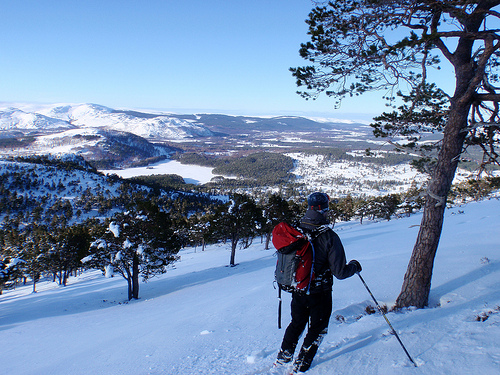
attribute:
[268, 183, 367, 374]
man — skiing, shadowing, here, standing, shadowy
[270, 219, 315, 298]
backpack — red, here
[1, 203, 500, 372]
slope — snowy, here, high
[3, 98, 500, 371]
snow — laying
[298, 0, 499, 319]
tree — tall, growing, here, snowy, shadowy, leafless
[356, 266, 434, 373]
ski pole — standing, black, here, metal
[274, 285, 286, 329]
strap — hanging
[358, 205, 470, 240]
stand — here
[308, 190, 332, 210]
helmet — here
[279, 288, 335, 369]
pants — here, dark, black